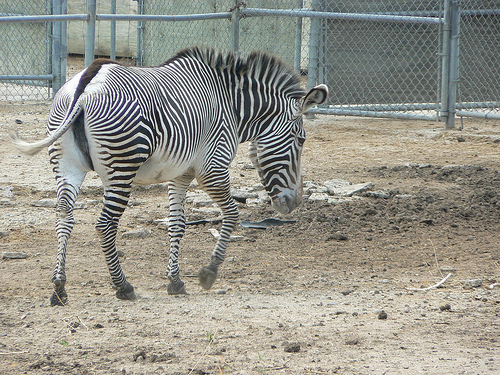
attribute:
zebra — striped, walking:
[5, 46, 328, 308]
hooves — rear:
[34, 277, 148, 314]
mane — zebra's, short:
[159, 41, 310, 97]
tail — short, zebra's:
[7, 80, 103, 175]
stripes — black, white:
[131, 72, 229, 157]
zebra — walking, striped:
[13, 38, 334, 323]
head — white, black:
[242, 58, 334, 222]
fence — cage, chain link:
[3, 0, 499, 137]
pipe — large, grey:
[6, 5, 473, 39]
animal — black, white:
[13, 34, 330, 324]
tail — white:
[12, 89, 89, 167]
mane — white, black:
[166, 37, 313, 94]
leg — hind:
[87, 188, 167, 323]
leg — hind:
[34, 152, 92, 318]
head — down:
[251, 54, 343, 220]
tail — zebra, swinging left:
[4, 65, 100, 168]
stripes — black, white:
[167, 75, 234, 138]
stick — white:
[402, 268, 470, 304]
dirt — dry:
[3, 87, 497, 373]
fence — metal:
[3, 3, 498, 121]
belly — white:
[127, 152, 207, 192]